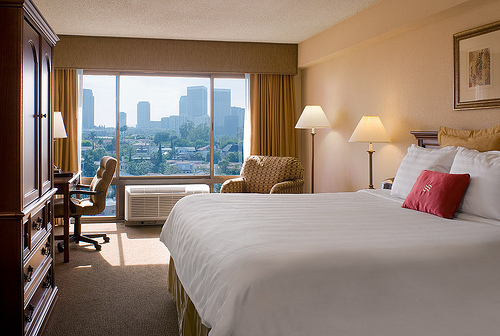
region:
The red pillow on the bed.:
[399, 162, 479, 228]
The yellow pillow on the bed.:
[427, 128, 497, 160]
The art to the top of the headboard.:
[431, 15, 498, 112]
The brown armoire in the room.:
[4, 0, 66, 330]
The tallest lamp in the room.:
[294, 100, 344, 190]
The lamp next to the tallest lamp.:
[346, 106, 398, 181]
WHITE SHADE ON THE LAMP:
[353, 113, 387, 142]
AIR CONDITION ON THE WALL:
[126, 185, 175, 215]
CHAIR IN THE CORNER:
[224, 157, 305, 192]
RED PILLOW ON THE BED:
[408, 172, 471, 214]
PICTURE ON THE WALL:
[451, 24, 496, 109]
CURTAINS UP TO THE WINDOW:
[258, 75, 291, 152]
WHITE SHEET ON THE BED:
[327, 211, 373, 265]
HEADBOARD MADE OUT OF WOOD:
[414, 130, 438, 145]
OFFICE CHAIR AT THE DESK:
[75, 153, 120, 244]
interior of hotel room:
[3, 1, 497, 333]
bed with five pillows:
[163, 128, 498, 333]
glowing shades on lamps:
[295, 104, 390, 191]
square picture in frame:
[451, 20, 498, 110]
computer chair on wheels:
[53, 155, 118, 252]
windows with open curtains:
[52, 74, 294, 181]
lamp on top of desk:
[52, 112, 77, 259]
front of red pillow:
[402, 168, 472, 218]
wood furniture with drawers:
[1, 1, 58, 335]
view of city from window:
[82, 76, 242, 169]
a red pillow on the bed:
[406, 170, 463, 217]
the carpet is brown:
[90, 288, 157, 333]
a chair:
[88, 149, 120, 209]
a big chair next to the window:
[240, 157, 295, 189]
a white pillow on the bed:
[468, 156, 498, 190]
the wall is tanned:
[376, 63, 422, 105]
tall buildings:
[176, 85, 211, 117]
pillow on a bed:
[390, 170, 466, 216]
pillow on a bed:
[400, 141, 446, 166]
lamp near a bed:
[351, 108, 383, 176]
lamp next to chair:
[290, 95, 328, 168]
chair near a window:
[236, 146, 302, 183]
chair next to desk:
[95, 148, 115, 256]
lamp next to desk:
[56, 110, 67, 145]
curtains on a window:
[241, 62, 291, 132]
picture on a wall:
[442, 34, 498, 112]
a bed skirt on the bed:
[160, 262, 190, 309]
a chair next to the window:
[236, 144, 298, 195]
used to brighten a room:
[348, 116, 391, 187]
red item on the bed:
[401, 169, 470, 218]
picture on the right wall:
[453, 17, 497, 112]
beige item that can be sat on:
[223, 153, 302, 193]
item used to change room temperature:
[124, 186, 209, 221]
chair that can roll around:
[56, 155, 117, 250]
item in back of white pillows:
[439, 125, 499, 150]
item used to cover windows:
[250, 68, 300, 156]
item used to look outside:
[78, 68, 246, 173]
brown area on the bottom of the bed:
[166, 262, 206, 334]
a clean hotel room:
[2, 4, 490, 327]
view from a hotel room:
[75, 71, 247, 186]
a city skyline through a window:
[75, 88, 248, 148]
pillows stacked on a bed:
[390, 107, 499, 233]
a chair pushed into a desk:
[48, 146, 127, 265]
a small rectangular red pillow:
[397, 156, 473, 224]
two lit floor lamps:
[282, 91, 390, 200]